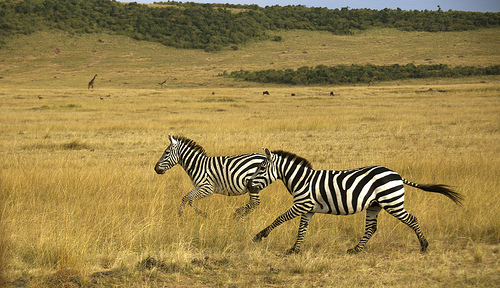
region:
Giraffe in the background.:
[75, 70, 100, 100]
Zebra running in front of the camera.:
[254, 150, 341, 210]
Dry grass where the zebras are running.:
[55, 167, 110, 229]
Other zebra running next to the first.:
[159, 140, 205, 202]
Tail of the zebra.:
[422, 180, 479, 216]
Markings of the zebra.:
[325, 179, 370, 203]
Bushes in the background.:
[301, 62, 396, 81]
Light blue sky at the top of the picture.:
[417, 3, 482, 8]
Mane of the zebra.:
[277, 150, 314, 167]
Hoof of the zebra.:
[416, 239, 442, 254]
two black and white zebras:
[159, 122, 429, 251]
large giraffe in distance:
[80, 60, 124, 104]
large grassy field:
[47, 98, 451, 127]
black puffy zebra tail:
[394, 167, 484, 208]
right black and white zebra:
[240, 155, 455, 247]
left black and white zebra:
[131, 103, 290, 218]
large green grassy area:
[197, 0, 470, 82]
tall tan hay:
[30, 215, 367, 285]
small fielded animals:
[193, 84, 350, 115]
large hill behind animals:
[14, 0, 469, 117]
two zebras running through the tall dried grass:
[142, 125, 472, 269]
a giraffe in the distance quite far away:
[76, 65, 104, 97]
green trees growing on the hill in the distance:
[0, 1, 498, 55]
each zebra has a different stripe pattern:
[130, 124, 470, 265]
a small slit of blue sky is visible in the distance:
[128, 0, 498, 10]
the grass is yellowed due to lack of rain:
[2, 102, 498, 287]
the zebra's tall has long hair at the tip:
[400, 171, 465, 208]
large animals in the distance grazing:
[254, 84, 344, 104]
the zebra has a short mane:
[244, 145, 316, 198]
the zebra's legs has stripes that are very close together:
[239, 206, 440, 260]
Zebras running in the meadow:
[142, 121, 483, 259]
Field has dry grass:
[5, 35, 496, 286]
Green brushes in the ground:
[4, 2, 494, 46]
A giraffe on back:
[81, 68, 103, 92]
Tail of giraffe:
[402, 171, 473, 205]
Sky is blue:
[217, 0, 498, 12]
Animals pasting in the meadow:
[201, 84, 349, 102]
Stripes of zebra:
[274, 165, 402, 216]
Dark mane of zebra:
[265, 142, 317, 174]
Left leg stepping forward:
[242, 201, 307, 245]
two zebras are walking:
[145, 133, 443, 242]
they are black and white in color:
[156, 135, 423, 235]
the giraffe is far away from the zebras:
[82, 67, 104, 92]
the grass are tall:
[17, 171, 174, 218]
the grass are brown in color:
[10, 181, 177, 255]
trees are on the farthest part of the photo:
[4, 1, 494, 53]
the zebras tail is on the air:
[404, 181, 473, 198]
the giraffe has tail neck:
[91, 71, 97, 81]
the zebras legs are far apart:
[248, 211, 311, 263]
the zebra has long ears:
[262, 148, 271, 160]